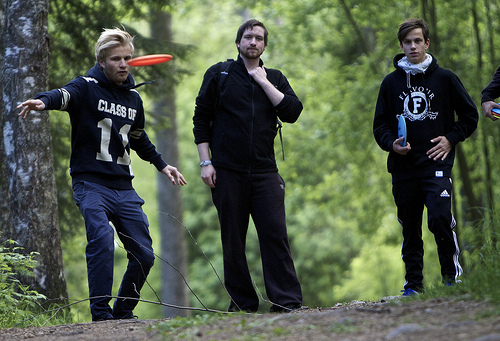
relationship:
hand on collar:
[247, 72, 272, 88] [233, 62, 276, 76]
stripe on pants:
[448, 195, 464, 276] [376, 183, 466, 288]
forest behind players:
[134, 1, 409, 118] [42, 29, 462, 263]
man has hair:
[213, 15, 287, 310] [245, 50, 264, 63]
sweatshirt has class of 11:
[40, 79, 188, 189] [94, 96, 145, 176]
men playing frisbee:
[42, 29, 462, 263] [385, 115, 417, 146]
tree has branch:
[14, 0, 116, 252] [70, 293, 283, 321]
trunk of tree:
[14, 75, 61, 294] [14, 0, 116, 252]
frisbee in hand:
[385, 115, 417, 146] [247, 72, 272, 88]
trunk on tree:
[14, 75, 61, 294] [14, 0, 116, 252]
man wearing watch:
[213, 15, 287, 310] [188, 158, 220, 164]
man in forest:
[213, 15, 287, 310] [134, 1, 409, 118]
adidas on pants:
[434, 188, 457, 203] [376, 183, 466, 288]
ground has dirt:
[24, 286, 499, 340] [328, 307, 478, 331]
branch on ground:
[70, 293, 283, 321] [24, 286, 499, 340]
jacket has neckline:
[202, 66, 296, 138] [233, 55, 278, 70]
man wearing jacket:
[213, 15, 287, 310] [202, 66, 296, 138]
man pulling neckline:
[213, 15, 287, 310] [233, 55, 278, 70]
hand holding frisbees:
[476, 101, 500, 118] [482, 97, 499, 128]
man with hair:
[213, 15, 287, 310] [245, 50, 264, 63]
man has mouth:
[213, 15, 287, 310] [246, 46, 262, 53]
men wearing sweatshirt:
[37, 28, 184, 316] [20, 79, 188, 189]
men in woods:
[37, 35, 480, 173] [24, 9, 481, 191]